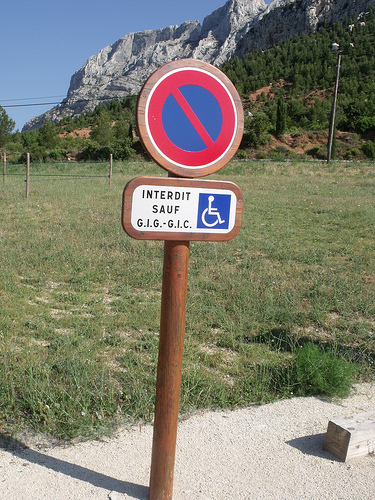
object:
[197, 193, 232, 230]
handicap symbol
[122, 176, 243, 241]
sign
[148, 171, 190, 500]
pole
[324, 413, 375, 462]
railroad tie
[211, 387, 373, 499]
ground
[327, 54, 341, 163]
telephone pole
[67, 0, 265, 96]
mountain top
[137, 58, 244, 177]
sign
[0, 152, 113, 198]
fence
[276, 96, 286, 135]
trees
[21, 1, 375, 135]
mountain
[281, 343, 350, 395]
plants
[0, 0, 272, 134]
sky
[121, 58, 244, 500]
sign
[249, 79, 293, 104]
area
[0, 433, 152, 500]
shadow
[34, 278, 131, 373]
empty patches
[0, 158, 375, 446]
grass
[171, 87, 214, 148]
diagonal line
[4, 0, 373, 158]
area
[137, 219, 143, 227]
letter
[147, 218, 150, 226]
letter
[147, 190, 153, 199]
letter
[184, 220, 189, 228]
letter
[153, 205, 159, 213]
letter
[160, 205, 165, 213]
letter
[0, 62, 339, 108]
power lines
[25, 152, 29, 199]
fence post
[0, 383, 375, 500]
gravel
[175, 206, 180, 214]
letter